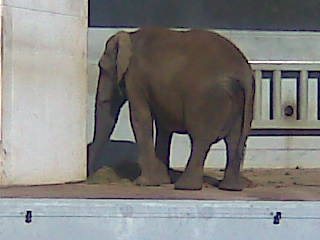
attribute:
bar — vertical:
[296, 70, 307, 121]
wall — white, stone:
[3, 3, 91, 185]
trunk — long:
[80, 80, 123, 178]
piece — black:
[16, 207, 42, 224]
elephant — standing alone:
[93, 22, 263, 229]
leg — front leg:
[129, 107, 170, 185]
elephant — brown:
[91, 17, 259, 191]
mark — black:
[23, 209, 32, 223]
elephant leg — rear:
[165, 117, 221, 207]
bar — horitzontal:
[247, 117, 319, 133]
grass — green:
[95, 163, 124, 184]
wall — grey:
[27, 206, 263, 232]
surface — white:
[0, 0, 87, 186]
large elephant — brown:
[94, 26, 256, 191]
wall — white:
[19, 36, 77, 149]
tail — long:
[235, 73, 254, 165]